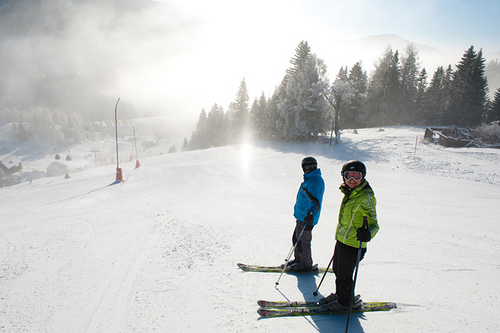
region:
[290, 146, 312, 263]
skier in blue jacket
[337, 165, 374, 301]
skier in yellow jacket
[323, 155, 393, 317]
skier holding ski poles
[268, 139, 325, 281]
skier wearing grey cap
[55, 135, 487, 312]
a lot of snow on the ground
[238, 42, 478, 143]
pine trees covered in snow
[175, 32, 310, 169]
sun shining behind the trees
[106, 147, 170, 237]
orange cones in the snow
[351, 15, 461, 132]
mountains behind the trees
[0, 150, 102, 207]
houses and buildings below the hill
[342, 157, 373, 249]
Skier in bright green coat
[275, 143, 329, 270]
Skier in medium blue coat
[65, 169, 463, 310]
powdery white snow slope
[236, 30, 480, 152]
Snow covered pine trees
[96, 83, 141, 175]
Metal pole on ski slope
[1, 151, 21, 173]
Small wooden lodging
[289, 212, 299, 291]
long ski poles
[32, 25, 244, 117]
Clouds rolling in above mountain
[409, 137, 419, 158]
orange pole on snow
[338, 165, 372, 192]
orange ski goggles on person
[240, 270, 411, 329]
these are snow skis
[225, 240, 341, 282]
these are snow skis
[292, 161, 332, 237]
this is a blue jacket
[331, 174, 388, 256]
this is a green jacket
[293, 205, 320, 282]
these are black pants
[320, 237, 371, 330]
these are snow pants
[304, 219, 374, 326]
these are ski poles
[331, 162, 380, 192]
these are the goggles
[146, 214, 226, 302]
this is the snow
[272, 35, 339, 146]
this is the tree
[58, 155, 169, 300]
the snow is white and clear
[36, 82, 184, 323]
the snow is white and clear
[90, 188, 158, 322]
the snow is white and clear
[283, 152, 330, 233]
Blue snow coat on skier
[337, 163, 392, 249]
Green snow coat on skier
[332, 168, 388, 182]
Orange snow goggles on skier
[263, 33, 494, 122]
Snow covered pine trees on slope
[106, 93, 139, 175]
Tall polls on snow slope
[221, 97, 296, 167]
Sun glare shining off mountain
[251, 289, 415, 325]
Set of yellow and green skis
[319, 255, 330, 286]
Ski pole touching snow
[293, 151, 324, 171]
Ski helmet on person in blue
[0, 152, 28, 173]
Small cabin at bottom of slope